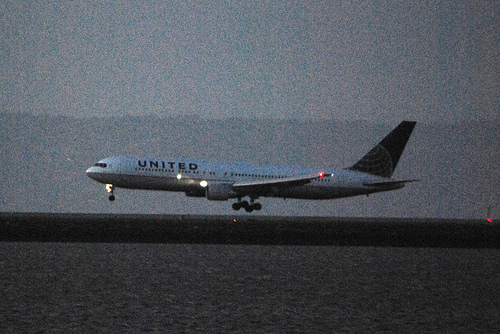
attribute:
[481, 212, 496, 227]
light — red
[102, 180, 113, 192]
light — White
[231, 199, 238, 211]
wheel — back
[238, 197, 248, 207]
wheel — back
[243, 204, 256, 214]
wheel — back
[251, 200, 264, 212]
wheel — back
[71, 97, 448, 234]
plane — flying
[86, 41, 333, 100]
sky — beautiful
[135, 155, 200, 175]
letters — black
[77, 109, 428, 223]
plane — grey, white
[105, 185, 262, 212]
gear — black